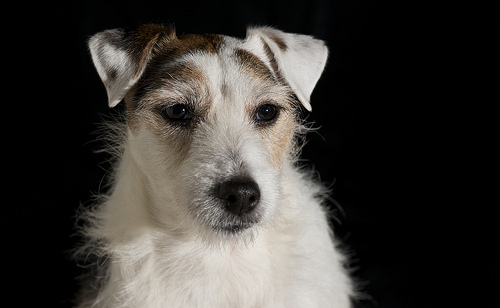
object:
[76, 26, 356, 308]
dog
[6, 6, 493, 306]
picture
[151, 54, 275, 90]
forehead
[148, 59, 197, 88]
marks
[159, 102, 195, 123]
eye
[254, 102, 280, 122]
eye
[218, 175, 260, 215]
black nose